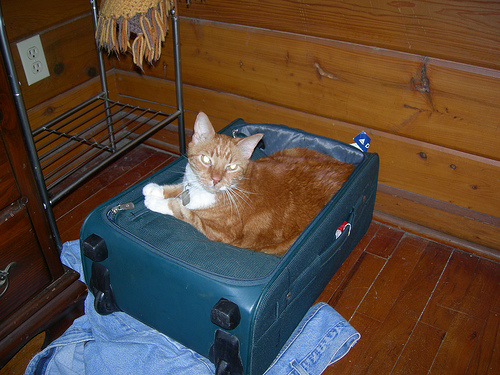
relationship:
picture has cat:
[3, 4, 494, 374] [138, 113, 357, 247]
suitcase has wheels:
[70, 116, 383, 366] [82, 291, 246, 374]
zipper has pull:
[105, 200, 142, 229] [110, 201, 139, 213]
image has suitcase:
[3, 4, 494, 374] [70, 116, 383, 366]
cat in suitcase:
[138, 113, 357, 247] [70, 116, 383, 366]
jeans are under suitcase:
[70, 315, 164, 369] [70, 116, 383, 366]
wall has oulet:
[391, 36, 487, 213] [14, 34, 51, 88]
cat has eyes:
[138, 113, 357, 247] [197, 152, 238, 172]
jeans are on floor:
[70, 315, 164, 369] [363, 262, 491, 368]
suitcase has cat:
[70, 116, 383, 366] [138, 113, 357, 247]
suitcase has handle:
[70, 116, 383, 366] [288, 202, 385, 314]